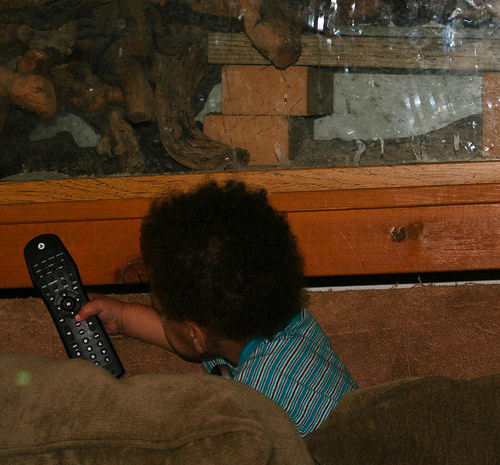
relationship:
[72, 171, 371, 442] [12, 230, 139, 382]
boy has a remote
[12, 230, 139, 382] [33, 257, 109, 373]
remote has buttons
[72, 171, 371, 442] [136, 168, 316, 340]
boy has hair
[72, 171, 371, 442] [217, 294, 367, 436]
boy has a shirt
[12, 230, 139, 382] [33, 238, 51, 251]
remote has a logo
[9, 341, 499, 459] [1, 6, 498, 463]
couch in room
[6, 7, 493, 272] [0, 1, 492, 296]
wood in background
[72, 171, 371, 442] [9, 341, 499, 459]
boy on couch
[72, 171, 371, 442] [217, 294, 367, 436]
boy wearing shirt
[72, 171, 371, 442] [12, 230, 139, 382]
boy holding remote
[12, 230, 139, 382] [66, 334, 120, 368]
remote has white numbers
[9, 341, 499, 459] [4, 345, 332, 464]
couch has cushions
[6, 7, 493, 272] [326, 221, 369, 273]
wood has a scratch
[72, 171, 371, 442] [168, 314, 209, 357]
boy hair an ear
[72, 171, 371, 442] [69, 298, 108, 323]
boy has a thumb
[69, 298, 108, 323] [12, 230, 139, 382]
thumb on remote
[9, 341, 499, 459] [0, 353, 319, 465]
couch has pillow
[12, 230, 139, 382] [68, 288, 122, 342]
remote in boy's hand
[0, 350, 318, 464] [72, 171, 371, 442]
pillow in front of boy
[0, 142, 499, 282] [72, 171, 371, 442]
wood case behind boy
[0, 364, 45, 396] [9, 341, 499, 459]
spot on couch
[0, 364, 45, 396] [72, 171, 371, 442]
spot behind boy